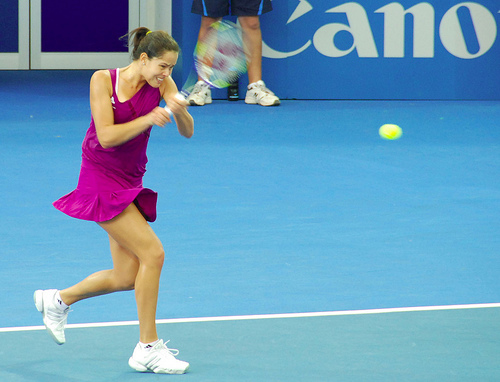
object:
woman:
[29, 24, 194, 375]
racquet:
[162, 18, 257, 117]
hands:
[148, 104, 173, 129]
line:
[0, 300, 499, 333]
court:
[0, 97, 498, 381]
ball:
[376, 121, 403, 142]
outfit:
[50, 66, 165, 224]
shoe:
[125, 335, 190, 376]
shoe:
[31, 286, 76, 346]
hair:
[115, 25, 180, 61]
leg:
[93, 200, 166, 342]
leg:
[58, 231, 140, 306]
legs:
[232, 14, 263, 87]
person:
[183, 0, 281, 108]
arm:
[88, 75, 172, 150]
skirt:
[49, 154, 159, 223]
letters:
[435, 0, 498, 61]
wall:
[170, 0, 499, 102]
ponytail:
[117, 26, 151, 55]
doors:
[29, 0, 142, 71]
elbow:
[95, 130, 119, 150]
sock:
[137, 336, 164, 349]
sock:
[52, 289, 71, 311]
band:
[142, 30, 152, 36]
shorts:
[188, 0, 276, 20]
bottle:
[225, 69, 242, 102]